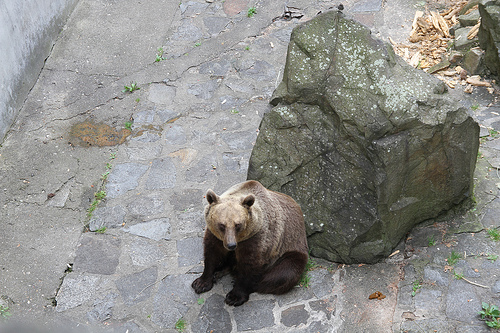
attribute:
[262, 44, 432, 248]
stone — flat, big, present, here, gray, huge, large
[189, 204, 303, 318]
bear — sitting, large, black, here, brown, grizzly, present, looking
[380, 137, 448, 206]
rock — grey, small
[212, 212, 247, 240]
eye — black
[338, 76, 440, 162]
rocks — orange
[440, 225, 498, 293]
plants — growing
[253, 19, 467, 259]
boulder — behind, large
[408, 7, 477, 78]
wood — laying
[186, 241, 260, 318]
paws — large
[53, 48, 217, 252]
platform — stone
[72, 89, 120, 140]
poop — smeared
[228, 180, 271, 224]
ear — fuzzy